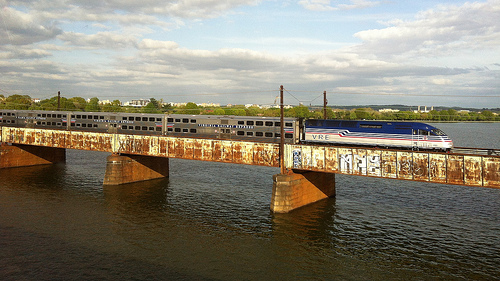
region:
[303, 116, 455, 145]
a long blue train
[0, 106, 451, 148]
a blue train pulling passenger cars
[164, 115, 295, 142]
a long passenger train car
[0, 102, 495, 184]
a train crossing a rusty bridge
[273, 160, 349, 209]
a rusty orange bridge pillar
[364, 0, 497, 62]
a cloudy day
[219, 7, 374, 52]
a clear blue sky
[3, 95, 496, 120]
a row of trees and bushes in the distance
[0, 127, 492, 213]
a rusty orange and white bridge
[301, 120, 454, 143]
a red white and blue train car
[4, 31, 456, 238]
Train travelling on a bridge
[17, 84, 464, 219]
Blue, red, and white train travelling on a bridge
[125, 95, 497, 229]
Train on a rusty bridge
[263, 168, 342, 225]
Pillar under a bridge with rust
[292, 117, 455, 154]
Front car of a train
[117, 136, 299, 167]
The sides of a bridge with rust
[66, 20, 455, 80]
Cloudy skies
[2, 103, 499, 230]
Train over a bridge with murky water.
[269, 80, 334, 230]
Electrical poles on a bridge with train tracks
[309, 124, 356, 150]
VRE sign and logo on the side of a train car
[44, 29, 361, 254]
a train on a bridge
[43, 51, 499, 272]
a train on a track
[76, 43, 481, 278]
a train on a train bridge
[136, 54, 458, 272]
a bridge with a track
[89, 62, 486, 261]
a bridge with a train track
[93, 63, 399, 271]
a train moving above water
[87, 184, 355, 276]
a body of water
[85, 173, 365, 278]
a body of calm water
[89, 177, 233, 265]
a body of water that is calm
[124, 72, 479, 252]
a bridge with a train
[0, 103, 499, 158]
Train moving on tracks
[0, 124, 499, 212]
Train bridge with chipping paint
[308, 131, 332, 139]
Blue letters on a train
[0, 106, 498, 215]
Train crossing a river by bridge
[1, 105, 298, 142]
Gray metal train cars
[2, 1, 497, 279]
Cloudy sky and wide river scene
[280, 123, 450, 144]
Blue and red stripes on a train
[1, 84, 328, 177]
Power lines on rusted poles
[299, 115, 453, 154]
Blue and white front train car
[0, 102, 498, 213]
Train crossing a bridge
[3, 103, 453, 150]
A fast train on a bridge.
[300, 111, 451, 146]
The engine of the train.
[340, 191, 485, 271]
A river.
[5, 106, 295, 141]
Train cars.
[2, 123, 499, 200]
A bridge over a river.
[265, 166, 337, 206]
The supports for the bridge.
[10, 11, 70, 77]
Fluffy clouds cover the sky.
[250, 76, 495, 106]
Power lines.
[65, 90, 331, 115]
Trees in the background.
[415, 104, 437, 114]
A factory towers in the background.